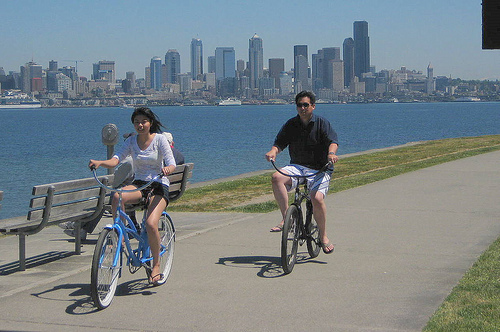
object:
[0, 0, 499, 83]
sky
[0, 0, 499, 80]
clouds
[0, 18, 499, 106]
city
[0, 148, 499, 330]
sidewalk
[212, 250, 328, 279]
shadow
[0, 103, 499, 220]
water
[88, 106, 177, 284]
woman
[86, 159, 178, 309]
bicycle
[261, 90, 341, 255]
man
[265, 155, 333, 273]
bicycle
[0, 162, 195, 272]
bench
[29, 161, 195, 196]
plank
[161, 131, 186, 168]
person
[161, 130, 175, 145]
hair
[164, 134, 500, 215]
patch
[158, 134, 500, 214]
grass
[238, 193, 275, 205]
spots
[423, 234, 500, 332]
patch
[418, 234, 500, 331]
grass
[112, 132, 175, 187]
shirt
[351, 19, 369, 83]
building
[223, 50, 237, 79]
building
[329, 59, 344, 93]
building